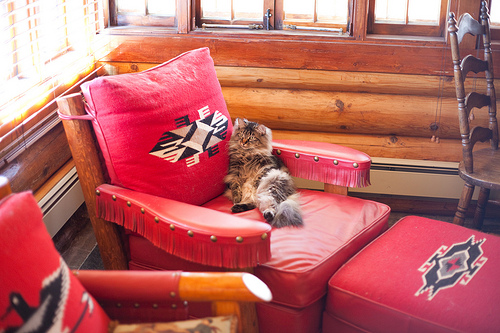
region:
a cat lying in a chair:
[211, 102, 299, 222]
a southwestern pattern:
[409, 232, 499, 299]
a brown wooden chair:
[431, 7, 498, 213]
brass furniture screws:
[93, 186, 128, 203]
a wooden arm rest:
[181, 266, 269, 305]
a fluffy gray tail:
[274, 202, 305, 234]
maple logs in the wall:
[248, 33, 449, 133]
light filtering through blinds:
[4, 6, 95, 80]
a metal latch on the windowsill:
[261, 7, 278, 32]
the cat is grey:
[235, 123, 301, 221]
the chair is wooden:
[85, 80, 370, 272]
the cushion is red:
[88, 53, 245, 198]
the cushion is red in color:
[348, 214, 495, 322]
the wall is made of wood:
[322, 43, 457, 161]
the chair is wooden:
[438, 15, 497, 223]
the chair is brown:
[445, 12, 498, 241]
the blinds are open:
[21, 13, 121, 75]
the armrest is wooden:
[93, 254, 273, 331]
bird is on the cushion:
[7, 278, 118, 329]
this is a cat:
[228, 115, 293, 211]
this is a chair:
[86, 57, 321, 235]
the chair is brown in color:
[66, 110, 90, 180]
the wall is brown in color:
[320, 90, 390, 135]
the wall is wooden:
[346, 87, 411, 132]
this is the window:
[15, 1, 65, 66]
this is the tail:
[272, 197, 302, 224]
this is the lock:
[261, 6, 273, 33]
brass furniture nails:
[97, 189, 133, 207]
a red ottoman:
[324, 217, 491, 331]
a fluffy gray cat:
[224, 120, 291, 224]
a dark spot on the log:
[336, 94, 344, 111]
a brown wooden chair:
[441, 14, 493, 216]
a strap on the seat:
[59, 108, 99, 123]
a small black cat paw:
[229, 198, 259, 211]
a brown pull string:
[426, 40, 451, 142]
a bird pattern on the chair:
[7, 285, 102, 327]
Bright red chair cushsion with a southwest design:
[80, 43, 235, 207]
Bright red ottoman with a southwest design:
[325, 212, 498, 332]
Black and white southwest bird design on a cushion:
[1, 254, 96, 331]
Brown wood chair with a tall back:
[442, 1, 497, 225]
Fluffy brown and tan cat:
[222, 113, 304, 230]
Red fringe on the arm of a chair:
[91, 182, 274, 268]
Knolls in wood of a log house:
[252, 75, 441, 146]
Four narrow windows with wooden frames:
[100, 0, 477, 77]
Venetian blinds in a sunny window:
[0, 1, 110, 164]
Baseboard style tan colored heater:
[290, 155, 483, 207]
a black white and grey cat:
[224, 97, 306, 234]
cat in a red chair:
[49, 45, 394, 329]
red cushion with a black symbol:
[70, 35, 255, 213]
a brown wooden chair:
[430, 2, 498, 228]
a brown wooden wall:
[74, 28, 498, 198]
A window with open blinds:
[0, 0, 121, 174]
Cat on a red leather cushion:
[117, 116, 408, 308]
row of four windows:
[101, 0, 491, 45]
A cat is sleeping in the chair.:
[203, 118, 301, 220]